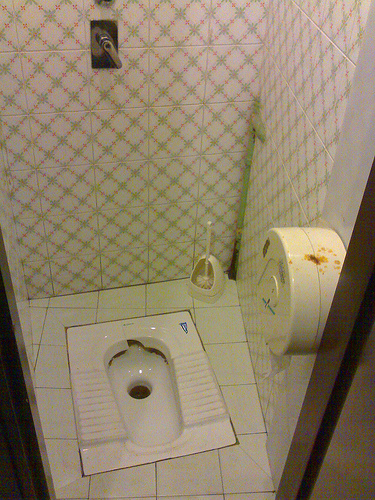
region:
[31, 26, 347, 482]
dirty third-world bathroom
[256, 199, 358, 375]
dirty white toilet paper dispenser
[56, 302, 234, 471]
white dirty squat toilet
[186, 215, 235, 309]
toilet scrub brush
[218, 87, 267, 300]
green bathroom pipe in the corner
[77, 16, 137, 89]
silver water handle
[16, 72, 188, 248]
patterned bathroom wall tile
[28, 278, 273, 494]
dirty tiled bathroom floor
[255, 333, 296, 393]
toilet paper coming out of dispenser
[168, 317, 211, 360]
logo on a squat toilet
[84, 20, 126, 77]
Flush for the toilet.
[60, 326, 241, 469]
Toilet is in the floor.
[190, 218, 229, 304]
Cleaning brush for the toilet.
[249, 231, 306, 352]
Toilet paper roll container.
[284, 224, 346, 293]
Vomit on the container.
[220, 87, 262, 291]
Cane against the wall.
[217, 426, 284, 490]
Crack in the tile.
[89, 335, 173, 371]
The toilet needs cleaned.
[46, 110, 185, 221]
Pattern on the wall paper.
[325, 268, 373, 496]
Part of the doorway.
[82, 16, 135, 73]
Flush for the toilet.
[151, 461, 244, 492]
The tiles are white.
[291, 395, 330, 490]
The door frame is brown.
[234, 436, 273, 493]
Crack in the tile.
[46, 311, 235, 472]
Toilet is in the floor.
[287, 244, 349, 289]
Vomit on the toilet paper holder.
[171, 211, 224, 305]
Toilet bowl cleaning brush in corner.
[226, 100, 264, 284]
Cane against the wall.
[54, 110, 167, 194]
Pink and green design on the wallpaper.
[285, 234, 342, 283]
yellow bathroom scum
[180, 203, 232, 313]
white plastic toilet bowl cleaner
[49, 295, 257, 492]
white ceramic pit toilet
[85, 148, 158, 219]
ceramic tile with flower design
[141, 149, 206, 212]
ceramic tile with flower design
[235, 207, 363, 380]
toilet paper dispenser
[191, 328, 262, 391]
white ceramic tile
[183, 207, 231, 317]
white plastic toilet bowl scrubber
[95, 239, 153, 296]
ceramic tile with flower design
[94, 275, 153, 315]
white ceramic tile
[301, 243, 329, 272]
brown speck on toilet dispenser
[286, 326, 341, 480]
solid brown pole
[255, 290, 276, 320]
small hole in toilet paper dispenser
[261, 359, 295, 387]
small piece of white toilet paper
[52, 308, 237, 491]
flat white toilet bowl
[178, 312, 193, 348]
blue symbol on toilet bowl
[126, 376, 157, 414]
round hole in toilet bowil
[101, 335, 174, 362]
brown spots in toilet bowl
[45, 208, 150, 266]
patterned tiles on toilet wall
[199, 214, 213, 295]
white toilet scrub brush